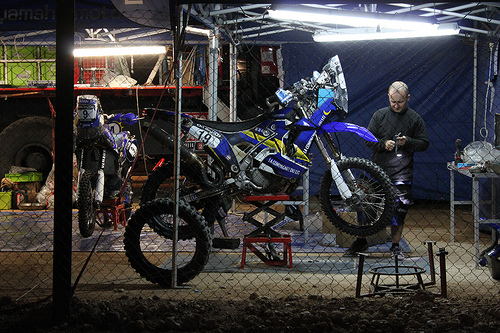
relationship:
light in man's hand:
[382, 130, 414, 165] [392, 132, 406, 151]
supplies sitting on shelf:
[79, 56, 154, 90] [3, 80, 203, 93]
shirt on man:
[363, 103, 431, 175] [341, 81, 430, 261]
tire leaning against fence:
[124, 197, 209, 284] [4, 5, 499, 331]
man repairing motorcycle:
[341, 81, 430, 261] [137, 101, 422, 201]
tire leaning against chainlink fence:
[124, 197, 209, 284] [0, 0, 499, 309]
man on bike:
[356, 74, 437, 266] [139, 56, 397, 241]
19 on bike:
[198, 131, 212, 144] [104, 73, 401, 293]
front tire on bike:
[319, 157, 397, 237] [55, 69, 157, 236]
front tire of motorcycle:
[306, 147, 400, 236] [117, 69, 403, 285]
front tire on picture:
[319, 157, 397, 237] [15, 19, 469, 312]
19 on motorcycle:
[198, 130, 211, 142] [123, 55, 400, 288]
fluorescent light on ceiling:
[268, 2, 460, 42] [268, 4, 458, 45]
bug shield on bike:
[304, 48, 356, 128] [129, 99, 411, 289]